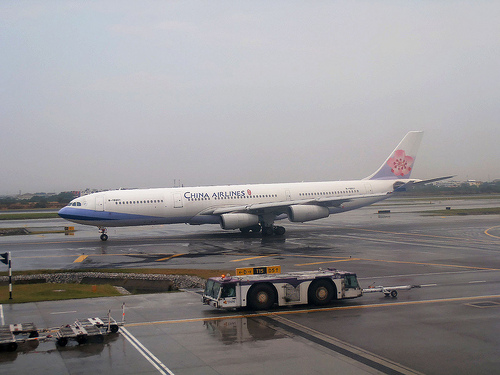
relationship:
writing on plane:
[184, 191, 210, 199] [57, 129, 458, 241]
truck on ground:
[205, 268, 364, 305] [11, 219, 496, 371]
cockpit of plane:
[62, 196, 85, 214] [57, 129, 458, 241]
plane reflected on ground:
[57, 129, 458, 241] [0, 193, 499, 373]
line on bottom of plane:
[57, 211, 119, 222] [57, 129, 458, 241]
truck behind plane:
[200, 266, 363, 309] [57, 129, 458, 241]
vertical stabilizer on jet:
[381, 132, 420, 177] [54, 141, 435, 228]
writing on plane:
[180, 185, 244, 202] [51, 123, 452, 255]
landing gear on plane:
[98, 232, 107, 242] [55, 135, 443, 232]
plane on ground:
[57, 129, 458, 241] [0, 193, 499, 373]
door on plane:
[88, 193, 110, 213] [57, 129, 458, 241]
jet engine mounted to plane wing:
[219, 212, 262, 230] [210, 192, 392, 215]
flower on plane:
[387, 150, 414, 179] [57, 129, 458, 241]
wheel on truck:
[245, 283, 279, 313] [200, 266, 363, 309]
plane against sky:
[57, 129, 458, 241] [0, 3, 497, 198]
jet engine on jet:
[215, 210, 263, 231] [52, 125, 459, 249]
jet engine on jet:
[285, 201, 334, 224] [52, 125, 459, 249]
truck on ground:
[200, 266, 363, 309] [0, 193, 499, 373]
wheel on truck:
[307, 276, 337, 306] [188, 232, 413, 329]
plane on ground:
[64, 129, 458, 249] [0, 193, 497, 369]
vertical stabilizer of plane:
[360, 130, 420, 181] [57, 129, 458, 241]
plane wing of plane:
[211, 189, 395, 216] [57, 129, 458, 241]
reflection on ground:
[198, 304, 363, 349] [0, 193, 499, 373]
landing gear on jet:
[98, 232, 107, 242] [80, 185, 367, 216]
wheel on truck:
[300, 273, 341, 320] [197, 257, 382, 337]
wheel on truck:
[245, 283, 279, 311] [197, 257, 382, 337]